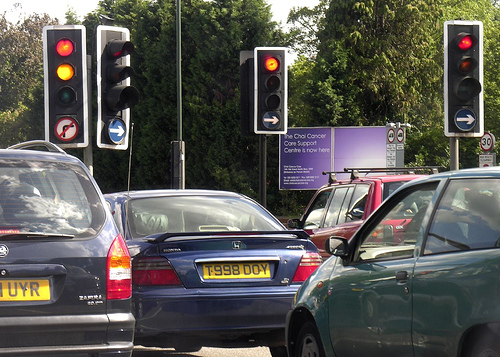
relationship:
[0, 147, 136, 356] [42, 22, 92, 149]
vehicle stopped at a traffic light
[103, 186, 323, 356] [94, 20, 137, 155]
vehicle stopped at a traffic light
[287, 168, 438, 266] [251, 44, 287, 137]
vehicle stopped at a traffic light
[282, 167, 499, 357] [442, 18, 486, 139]
vehicle stopped at a traffic light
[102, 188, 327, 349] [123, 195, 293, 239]
car has a rear window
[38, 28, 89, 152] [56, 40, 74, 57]
light has light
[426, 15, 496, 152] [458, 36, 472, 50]
light has light